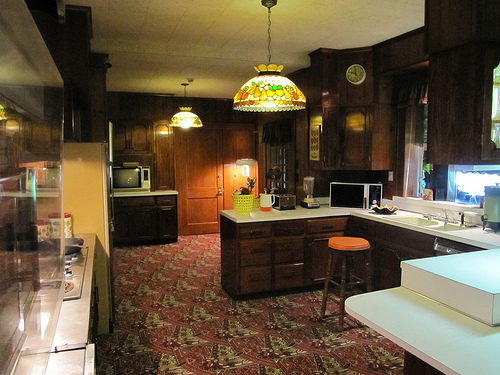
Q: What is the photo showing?
A: It is showing a kitchen.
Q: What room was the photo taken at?
A: It was taken at the kitchen.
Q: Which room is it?
A: It is a kitchen.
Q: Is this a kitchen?
A: Yes, it is a kitchen.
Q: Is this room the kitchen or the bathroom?
A: It is the kitchen.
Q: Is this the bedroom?
A: No, it is the kitchen.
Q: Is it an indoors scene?
A: Yes, it is indoors.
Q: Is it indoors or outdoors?
A: It is indoors.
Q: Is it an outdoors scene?
A: No, it is indoors.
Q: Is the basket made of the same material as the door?
A: No, the basket is made of plastic and the door is made of wood.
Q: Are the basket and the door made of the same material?
A: No, the basket is made of plastic and the door is made of wood.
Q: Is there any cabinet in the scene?
A: Yes, there is a cabinet.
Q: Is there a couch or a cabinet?
A: Yes, there is a cabinet.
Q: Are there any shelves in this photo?
A: No, there are no shelves.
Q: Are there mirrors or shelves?
A: No, there are no shelves or mirrors.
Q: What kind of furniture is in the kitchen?
A: The piece of furniture is a cabinet.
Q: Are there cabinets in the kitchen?
A: Yes, there is a cabinet in the kitchen.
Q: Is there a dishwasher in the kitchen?
A: No, there is a cabinet in the kitchen.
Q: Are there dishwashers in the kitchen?
A: No, there is a cabinet in the kitchen.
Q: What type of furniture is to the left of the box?
A: The piece of furniture is a cabinet.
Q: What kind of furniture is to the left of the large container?
A: The piece of furniture is a cabinet.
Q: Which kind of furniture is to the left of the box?
A: The piece of furniture is a cabinet.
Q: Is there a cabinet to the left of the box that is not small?
A: Yes, there is a cabinet to the left of the box.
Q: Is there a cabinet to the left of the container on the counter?
A: Yes, there is a cabinet to the left of the box.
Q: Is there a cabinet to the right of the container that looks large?
A: No, the cabinet is to the left of the box.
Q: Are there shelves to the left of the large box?
A: No, there is a cabinet to the left of the box.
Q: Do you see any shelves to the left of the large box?
A: No, there is a cabinet to the left of the box.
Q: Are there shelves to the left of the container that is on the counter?
A: No, there is a cabinet to the left of the box.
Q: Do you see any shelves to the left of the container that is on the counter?
A: No, there is a cabinet to the left of the box.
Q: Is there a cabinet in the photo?
A: Yes, there is a cabinet.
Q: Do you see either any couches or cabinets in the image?
A: Yes, there is a cabinet.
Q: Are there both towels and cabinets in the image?
A: No, there is a cabinet but no towels.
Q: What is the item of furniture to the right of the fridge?
A: The piece of furniture is a cabinet.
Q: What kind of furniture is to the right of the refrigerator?
A: The piece of furniture is a cabinet.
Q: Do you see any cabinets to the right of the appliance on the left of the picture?
A: Yes, there is a cabinet to the right of the refrigerator.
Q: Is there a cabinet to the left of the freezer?
A: No, the cabinet is to the right of the freezer.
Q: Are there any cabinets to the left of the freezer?
A: No, the cabinet is to the right of the freezer.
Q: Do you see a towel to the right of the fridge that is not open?
A: No, there is a cabinet to the right of the freezer.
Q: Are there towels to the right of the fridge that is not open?
A: No, there is a cabinet to the right of the freezer.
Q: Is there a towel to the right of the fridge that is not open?
A: No, there is a cabinet to the right of the freezer.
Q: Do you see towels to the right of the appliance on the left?
A: No, there is a cabinet to the right of the freezer.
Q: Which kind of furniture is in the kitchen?
A: The piece of furniture is a cabinet.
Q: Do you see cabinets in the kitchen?
A: Yes, there is a cabinet in the kitchen.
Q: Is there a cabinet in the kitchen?
A: Yes, there is a cabinet in the kitchen.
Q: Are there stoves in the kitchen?
A: No, there is a cabinet in the kitchen.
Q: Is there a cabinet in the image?
A: Yes, there is a cabinet.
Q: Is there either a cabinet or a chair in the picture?
A: Yes, there is a cabinet.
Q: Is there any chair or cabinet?
A: Yes, there is a cabinet.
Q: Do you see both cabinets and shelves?
A: No, there is a cabinet but no shelves.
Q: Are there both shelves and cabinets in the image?
A: No, there is a cabinet but no shelves.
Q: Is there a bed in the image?
A: No, there are no beds.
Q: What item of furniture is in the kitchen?
A: The piece of furniture is a cabinet.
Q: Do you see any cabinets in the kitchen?
A: Yes, there is a cabinet in the kitchen.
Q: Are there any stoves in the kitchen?
A: No, there is a cabinet in the kitchen.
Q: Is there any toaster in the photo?
A: Yes, there is a toaster.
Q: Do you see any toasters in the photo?
A: Yes, there is a toaster.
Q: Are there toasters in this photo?
A: Yes, there is a toaster.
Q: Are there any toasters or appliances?
A: Yes, there is a toaster.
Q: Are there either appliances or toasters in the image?
A: Yes, there is a toaster.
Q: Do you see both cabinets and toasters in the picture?
A: Yes, there are both a toaster and cabinets.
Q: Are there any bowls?
A: No, there are no bowls.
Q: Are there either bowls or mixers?
A: No, there are no bowls or mixers.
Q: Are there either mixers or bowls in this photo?
A: No, there are no bowls or mixers.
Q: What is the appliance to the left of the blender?
A: The appliance is a toaster.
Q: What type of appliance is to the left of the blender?
A: The appliance is a toaster.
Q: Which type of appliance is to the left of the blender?
A: The appliance is a toaster.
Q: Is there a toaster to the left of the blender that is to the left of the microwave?
A: Yes, there is a toaster to the left of the blender.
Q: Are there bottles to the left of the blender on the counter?
A: No, there is a toaster to the left of the blender.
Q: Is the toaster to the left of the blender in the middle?
A: Yes, the toaster is to the left of the blender.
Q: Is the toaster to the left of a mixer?
A: No, the toaster is to the left of the blender.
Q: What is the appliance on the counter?
A: The appliance is a toaster.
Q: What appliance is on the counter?
A: The appliance is a toaster.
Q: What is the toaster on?
A: The toaster is on the counter.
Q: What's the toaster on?
A: The toaster is on the counter.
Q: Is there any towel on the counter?
A: No, there is a toaster on the counter.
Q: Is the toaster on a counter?
A: Yes, the toaster is on a counter.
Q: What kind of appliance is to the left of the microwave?
A: The appliance is a toaster.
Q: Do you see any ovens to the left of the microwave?
A: No, there is a toaster to the left of the microwave.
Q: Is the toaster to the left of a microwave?
A: Yes, the toaster is to the left of a microwave.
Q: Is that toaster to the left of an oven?
A: No, the toaster is to the left of a microwave.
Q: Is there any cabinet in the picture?
A: Yes, there is a cabinet.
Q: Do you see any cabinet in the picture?
A: Yes, there is a cabinet.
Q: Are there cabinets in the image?
A: Yes, there is a cabinet.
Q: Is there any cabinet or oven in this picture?
A: Yes, there is a cabinet.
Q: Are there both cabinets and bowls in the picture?
A: No, there is a cabinet but no bowls.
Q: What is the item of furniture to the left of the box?
A: The piece of furniture is a cabinet.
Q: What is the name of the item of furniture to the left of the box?
A: The piece of furniture is a cabinet.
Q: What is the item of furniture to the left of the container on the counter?
A: The piece of furniture is a cabinet.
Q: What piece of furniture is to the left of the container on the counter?
A: The piece of furniture is a cabinet.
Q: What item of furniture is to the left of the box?
A: The piece of furniture is a cabinet.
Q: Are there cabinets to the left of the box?
A: Yes, there is a cabinet to the left of the box.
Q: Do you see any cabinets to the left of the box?
A: Yes, there is a cabinet to the left of the box.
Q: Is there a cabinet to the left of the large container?
A: Yes, there is a cabinet to the left of the box.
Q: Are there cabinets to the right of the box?
A: No, the cabinet is to the left of the box.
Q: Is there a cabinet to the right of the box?
A: No, the cabinet is to the left of the box.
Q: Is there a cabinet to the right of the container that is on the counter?
A: No, the cabinet is to the left of the box.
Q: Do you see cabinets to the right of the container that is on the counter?
A: No, the cabinet is to the left of the box.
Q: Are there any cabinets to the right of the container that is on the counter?
A: No, the cabinet is to the left of the box.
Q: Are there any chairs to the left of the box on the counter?
A: No, there is a cabinet to the left of the box.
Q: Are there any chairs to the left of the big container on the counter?
A: No, there is a cabinet to the left of the box.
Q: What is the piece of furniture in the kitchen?
A: The piece of furniture is a cabinet.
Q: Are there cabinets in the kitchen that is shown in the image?
A: Yes, there is a cabinet in the kitchen.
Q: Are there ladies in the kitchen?
A: No, there is a cabinet in the kitchen.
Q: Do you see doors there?
A: Yes, there is a door.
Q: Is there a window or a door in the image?
A: Yes, there is a door.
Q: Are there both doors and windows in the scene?
A: Yes, there are both a door and windows.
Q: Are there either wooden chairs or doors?
A: Yes, there is a wood door.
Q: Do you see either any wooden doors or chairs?
A: Yes, there is a wood door.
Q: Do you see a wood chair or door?
A: Yes, there is a wood door.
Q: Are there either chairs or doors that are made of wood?
A: Yes, the door is made of wood.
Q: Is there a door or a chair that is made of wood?
A: Yes, the door is made of wood.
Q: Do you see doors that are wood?
A: Yes, there is a wood door.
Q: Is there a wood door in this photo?
A: Yes, there is a wood door.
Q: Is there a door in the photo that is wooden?
A: Yes, there is a door that is wooden.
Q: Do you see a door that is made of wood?
A: Yes, there is a door that is made of wood.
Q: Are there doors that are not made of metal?
A: Yes, there is a door that is made of wood.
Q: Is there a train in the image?
A: No, there are no trains.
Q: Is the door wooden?
A: Yes, the door is wooden.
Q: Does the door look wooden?
A: Yes, the door is wooden.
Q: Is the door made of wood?
A: Yes, the door is made of wood.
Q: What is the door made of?
A: The door is made of wood.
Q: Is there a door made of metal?
A: No, there is a door but it is made of wood.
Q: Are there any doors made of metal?
A: No, there is a door but it is made of wood.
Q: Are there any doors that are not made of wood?
A: No, there is a door but it is made of wood.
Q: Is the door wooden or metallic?
A: The door is wooden.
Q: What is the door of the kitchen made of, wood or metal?
A: The door is made of wood.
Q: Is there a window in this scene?
A: Yes, there is a window.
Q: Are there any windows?
A: Yes, there is a window.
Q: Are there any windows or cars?
A: Yes, there is a window.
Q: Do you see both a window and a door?
A: Yes, there are both a window and a door.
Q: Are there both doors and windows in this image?
A: Yes, there are both a window and a door.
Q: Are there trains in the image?
A: No, there are no trains.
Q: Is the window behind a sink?
A: Yes, the window is behind a sink.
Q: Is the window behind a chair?
A: No, the window is behind a sink.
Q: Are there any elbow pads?
A: No, there are no elbow pads.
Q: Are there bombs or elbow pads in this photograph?
A: No, there are no elbow pads or bombs.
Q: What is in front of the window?
A: The sink is in front of the window.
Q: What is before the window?
A: The sink is in front of the window.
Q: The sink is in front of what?
A: The sink is in front of the window.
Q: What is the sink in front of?
A: The sink is in front of the window.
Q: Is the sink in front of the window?
A: Yes, the sink is in front of the window.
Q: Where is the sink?
A: The sink is in the kitchen.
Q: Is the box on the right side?
A: Yes, the box is on the right of the image.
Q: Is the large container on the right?
A: Yes, the box is on the right of the image.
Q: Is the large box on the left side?
A: No, the box is on the right of the image.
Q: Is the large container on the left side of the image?
A: No, the box is on the right of the image.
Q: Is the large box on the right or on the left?
A: The box is on the right of the image.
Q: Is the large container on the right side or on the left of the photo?
A: The box is on the right of the image.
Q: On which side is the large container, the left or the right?
A: The box is on the right of the image.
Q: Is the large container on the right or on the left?
A: The box is on the right of the image.